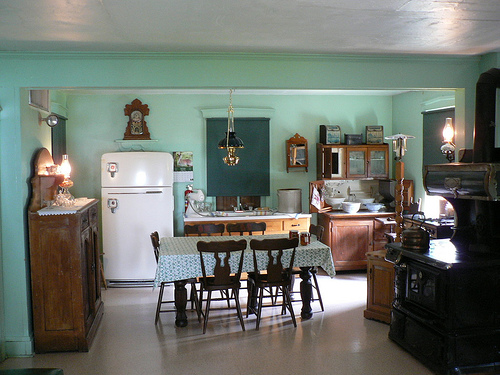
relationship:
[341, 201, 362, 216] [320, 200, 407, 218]
bowl on shelf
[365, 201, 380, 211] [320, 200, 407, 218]
bowl on shelf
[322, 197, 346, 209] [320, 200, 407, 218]
bowl on shelf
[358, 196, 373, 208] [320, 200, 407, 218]
bowl on shelf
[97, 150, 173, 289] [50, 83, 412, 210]
fridge next to wall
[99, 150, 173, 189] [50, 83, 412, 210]
freezer next to wall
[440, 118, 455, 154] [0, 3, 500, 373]
oil lamp in kitchen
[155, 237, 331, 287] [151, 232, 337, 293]
design on cloth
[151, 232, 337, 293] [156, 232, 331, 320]
cloth on table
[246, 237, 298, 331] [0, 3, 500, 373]
chair in kitchen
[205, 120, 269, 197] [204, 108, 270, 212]
shade on window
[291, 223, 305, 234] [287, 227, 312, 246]
lids on jars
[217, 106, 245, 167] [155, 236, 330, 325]
chandelier above table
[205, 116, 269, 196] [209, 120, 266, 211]
shade on window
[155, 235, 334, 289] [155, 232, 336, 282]
dots on tablecloth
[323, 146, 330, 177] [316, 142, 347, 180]
door on cabinet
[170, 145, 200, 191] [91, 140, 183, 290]
calender next to refrigerator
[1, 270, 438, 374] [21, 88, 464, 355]
linoleum floor of kitchen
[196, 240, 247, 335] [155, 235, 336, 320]
chair at dining table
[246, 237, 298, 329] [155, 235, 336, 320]
chair at dining table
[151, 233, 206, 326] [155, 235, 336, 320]
chair at dining table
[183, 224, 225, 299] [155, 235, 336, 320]
chair at dining table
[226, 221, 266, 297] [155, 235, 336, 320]
chair at dining table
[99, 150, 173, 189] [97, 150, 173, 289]
freezer on fridge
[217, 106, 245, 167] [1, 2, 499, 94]
chandelier on ceiling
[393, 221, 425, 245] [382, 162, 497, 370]
kerosene lantern on stove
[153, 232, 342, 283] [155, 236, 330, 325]
cloth on table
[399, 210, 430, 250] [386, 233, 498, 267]
kettle on top of stove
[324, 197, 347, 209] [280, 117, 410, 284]
bowl on sideboard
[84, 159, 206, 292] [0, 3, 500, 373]
fridge in kitchen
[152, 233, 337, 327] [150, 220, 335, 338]
dining table with chairs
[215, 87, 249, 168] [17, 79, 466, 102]
chandelier hanging from ceiling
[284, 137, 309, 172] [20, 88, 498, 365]
mirror in kitchen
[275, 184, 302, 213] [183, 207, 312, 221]
metal pot on counter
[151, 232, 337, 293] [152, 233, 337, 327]
cloth on dining table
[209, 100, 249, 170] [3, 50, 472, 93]
fixture hanging from ceiling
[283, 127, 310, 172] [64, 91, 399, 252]
mirror hanging on wall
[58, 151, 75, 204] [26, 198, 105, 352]
oil lamp on cabinet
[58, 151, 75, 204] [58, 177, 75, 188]
oil lamp with oil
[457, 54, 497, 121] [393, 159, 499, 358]
pipe connected to stove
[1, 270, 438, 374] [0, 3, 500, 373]
linoleum floor in kitchen